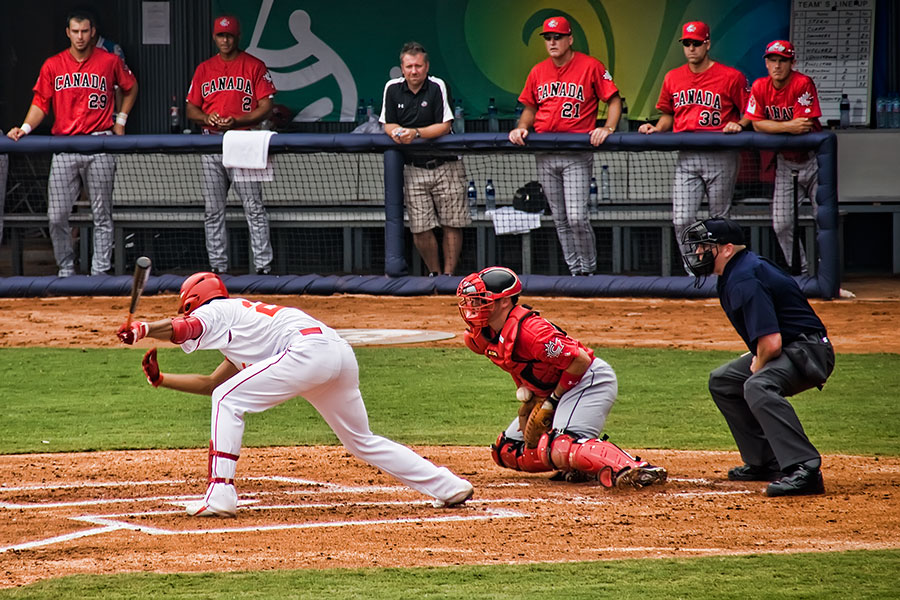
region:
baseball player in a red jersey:
[10, 14, 134, 275]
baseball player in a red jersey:
[188, 15, 278, 272]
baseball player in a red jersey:
[509, 15, 623, 274]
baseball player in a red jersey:
[637, 22, 748, 274]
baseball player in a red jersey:
[747, 40, 822, 272]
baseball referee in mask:
[674, 216, 836, 493]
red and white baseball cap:
[212, 13, 240, 34]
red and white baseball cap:
[539, 15, 572, 34]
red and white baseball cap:
[676, 19, 709, 40]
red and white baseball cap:
[766, 38, 794, 57]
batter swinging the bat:
[105, 230, 480, 512]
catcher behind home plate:
[449, 253, 665, 489]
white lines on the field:
[0, 429, 767, 596]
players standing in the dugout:
[9, 13, 834, 259]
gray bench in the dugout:
[14, 124, 897, 277]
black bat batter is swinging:
[127, 254, 152, 317]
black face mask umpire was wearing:
[671, 221, 721, 277]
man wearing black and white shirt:
[378, 33, 465, 278]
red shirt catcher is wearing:
[460, 320, 579, 388]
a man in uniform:
[763, 19, 845, 188]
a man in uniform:
[650, 184, 840, 423]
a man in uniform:
[501, 217, 593, 430]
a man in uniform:
[195, 269, 367, 505]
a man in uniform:
[617, 1, 779, 245]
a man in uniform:
[380, 6, 477, 260]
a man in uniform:
[182, 47, 284, 270]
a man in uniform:
[20, 22, 130, 199]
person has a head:
[461, 267, 522, 327]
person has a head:
[178, 266, 223, 309]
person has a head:
[687, 216, 737, 272]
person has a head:
[677, 21, 707, 67]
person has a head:
[542, 17, 570, 58]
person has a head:
[213, 15, 236, 49]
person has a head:
[66, 15, 90, 51]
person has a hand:
[208, 114, 228, 129]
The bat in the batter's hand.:
[126, 251, 156, 320]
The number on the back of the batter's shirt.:
[238, 300, 284, 319]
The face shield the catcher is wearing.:
[452, 269, 506, 350]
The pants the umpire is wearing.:
[713, 338, 837, 466]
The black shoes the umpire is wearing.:
[736, 462, 828, 498]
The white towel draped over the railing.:
[223, 122, 282, 187]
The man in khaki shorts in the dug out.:
[381, 41, 473, 272]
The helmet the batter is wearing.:
[174, 269, 231, 311]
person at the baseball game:
[100, 256, 479, 518]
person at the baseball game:
[450, 261, 666, 489]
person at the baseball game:
[675, 210, 830, 500]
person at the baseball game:
[636, 19, 755, 278]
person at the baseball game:
[507, 3, 620, 269]